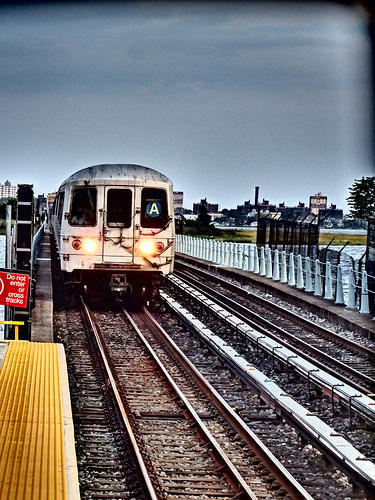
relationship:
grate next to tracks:
[0, 336, 71, 498] [80, 292, 326, 498]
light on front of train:
[130, 235, 165, 255] [42, 149, 175, 310]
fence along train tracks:
[174, 232, 373, 317] [51, 219, 374, 498]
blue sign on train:
[137, 199, 163, 215] [46, 160, 179, 304]